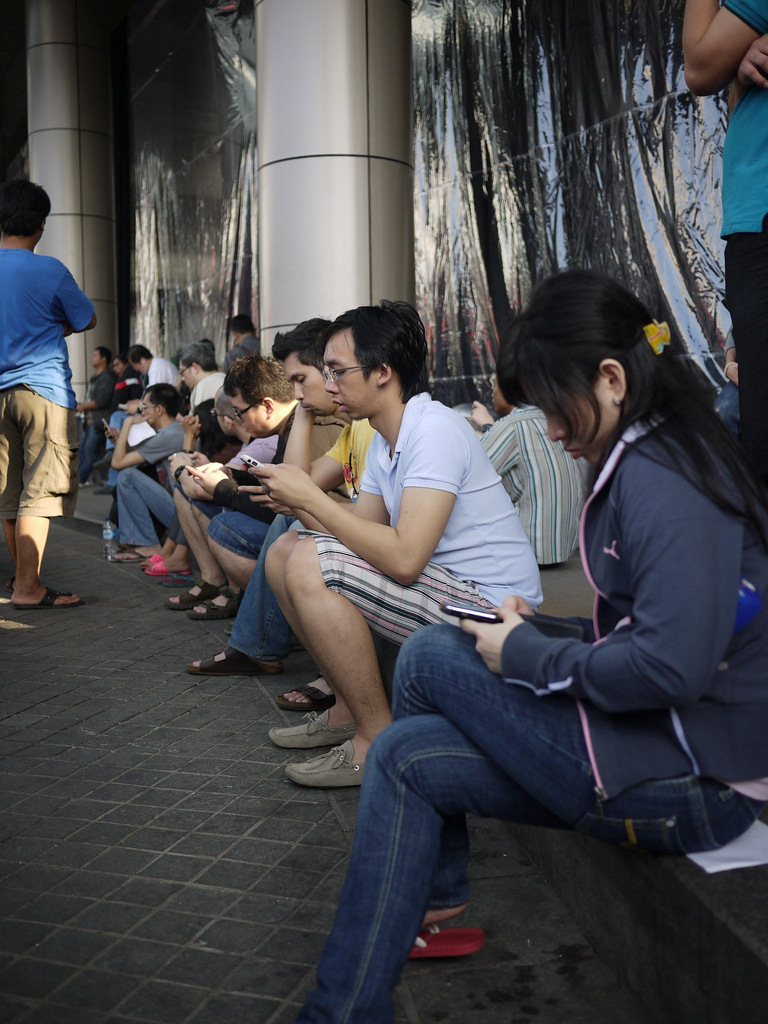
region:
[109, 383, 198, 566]
person sitting in front of building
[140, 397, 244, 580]
person sitting in front of building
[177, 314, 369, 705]
person sitting in front of building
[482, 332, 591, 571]
person sitting in front of building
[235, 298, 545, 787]
person sitting in front of building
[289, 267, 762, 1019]
person sitting in front of building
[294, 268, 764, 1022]
woman looking at her phone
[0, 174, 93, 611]
man wearing khaki shorts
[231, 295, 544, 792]
man wearing glasses looking a phone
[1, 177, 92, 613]
man in blue shirt wearing flip flops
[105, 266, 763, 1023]
group of people sitting down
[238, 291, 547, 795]
man wearing plaid shorts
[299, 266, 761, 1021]
woman with yellow bow in hair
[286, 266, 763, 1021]
woman wearing grey jacket with pink trim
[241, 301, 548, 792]
man with glasses wearing light blue shirt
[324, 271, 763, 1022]
woman is holding a mobile phone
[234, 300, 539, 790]
man is holding a mobile phone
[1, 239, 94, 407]
man is wearing a blue shirt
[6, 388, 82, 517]
man is wearing brown shorts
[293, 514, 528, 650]
man is wearing shorts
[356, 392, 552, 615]
man is wearing a white shirt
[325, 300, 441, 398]
man has short hair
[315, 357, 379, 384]
man has glasses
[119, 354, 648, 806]
a row of people sitting down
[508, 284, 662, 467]
a woman with black hair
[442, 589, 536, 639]
a woman holding a cell phone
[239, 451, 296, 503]
a man holding a cell phone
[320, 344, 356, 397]
a man wearing eye glasses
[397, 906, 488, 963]
a woman wearing a red flip flop shoe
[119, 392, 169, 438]
a man touching his face with his hand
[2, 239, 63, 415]
a man wearing a blue shirt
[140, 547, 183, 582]
a woman wearing pink shoes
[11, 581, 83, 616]
a man wearing brown sandles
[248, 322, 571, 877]
A man looking at his cellphone.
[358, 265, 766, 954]
A woman with long black hair.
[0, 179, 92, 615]
man standing wearing a blue t-shirt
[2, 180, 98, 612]
man in a blue t-shirt and sandals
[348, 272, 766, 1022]
woman sitting wearing blue jeans and red sandals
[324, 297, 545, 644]
man sitting wearing plaid shorts and glasses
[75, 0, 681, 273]
blue and grey mural abstract on the wall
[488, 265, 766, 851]
lady in a grey and pink jacket sitting on a wall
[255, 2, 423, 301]
pillar coulombs in front of the mural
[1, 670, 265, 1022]
gray paver bricks on the floor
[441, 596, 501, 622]
electronical device in asian students hands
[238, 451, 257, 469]
electronical device in asian students hands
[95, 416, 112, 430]
electronical device in asian students hands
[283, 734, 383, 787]
shoe on asian students foot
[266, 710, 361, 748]
shoe on asian students foot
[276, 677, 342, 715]
shoe on asian students foot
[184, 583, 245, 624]
shoe on asian students foot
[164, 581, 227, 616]
shoe on asian students foot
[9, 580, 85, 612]
shoe on asian students foot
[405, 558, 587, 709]
woman holding a phone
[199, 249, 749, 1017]
woman sitting on a concrete structure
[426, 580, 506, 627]
cellphone of the woman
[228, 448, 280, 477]
white colored cellphone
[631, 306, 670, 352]
yellow hairclip on woman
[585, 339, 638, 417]
left ear of woman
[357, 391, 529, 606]
white colored shirt on man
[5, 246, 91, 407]
blue colored shirt on man